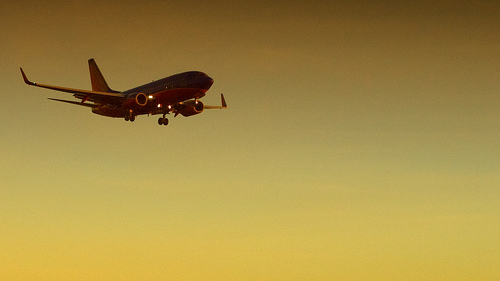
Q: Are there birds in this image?
A: No, there are no birds.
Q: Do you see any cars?
A: No, there are no cars.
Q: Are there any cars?
A: No, there are no cars.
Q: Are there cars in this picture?
A: No, there are no cars.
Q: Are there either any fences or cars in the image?
A: No, there are no cars or fences.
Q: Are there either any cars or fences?
A: No, there are no cars or fences.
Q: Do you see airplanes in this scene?
A: Yes, there is an airplane.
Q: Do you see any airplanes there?
A: Yes, there is an airplane.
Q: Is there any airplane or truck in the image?
A: Yes, there is an airplane.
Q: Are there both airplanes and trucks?
A: No, there is an airplane but no trucks.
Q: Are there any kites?
A: No, there are no kites.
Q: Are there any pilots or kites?
A: No, there are no kites or pilots.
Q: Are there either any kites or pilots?
A: No, there are no kites or pilots.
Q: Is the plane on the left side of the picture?
A: Yes, the plane is on the left of the image.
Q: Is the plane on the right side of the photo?
A: No, the plane is on the left of the image.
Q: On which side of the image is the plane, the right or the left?
A: The plane is on the left of the image.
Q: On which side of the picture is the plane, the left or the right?
A: The plane is on the left of the image.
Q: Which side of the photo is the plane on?
A: The plane is on the left of the image.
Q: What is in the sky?
A: The plane is in the sky.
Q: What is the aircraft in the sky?
A: The aircraft is an airplane.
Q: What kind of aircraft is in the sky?
A: The aircraft is an airplane.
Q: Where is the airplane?
A: The airplane is in the sky.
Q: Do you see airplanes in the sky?
A: Yes, there is an airplane in the sky.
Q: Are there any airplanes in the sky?
A: Yes, there is an airplane in the sky.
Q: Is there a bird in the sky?
A: No, there is an airplane in the sky.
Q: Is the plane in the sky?
A: Yes, the plane is in the sky.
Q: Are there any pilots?
A: No, there are no pilots.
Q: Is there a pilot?
A: No, there are no pilots.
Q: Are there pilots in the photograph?
A: No, there are no pilots.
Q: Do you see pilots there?
A: No, there are no pilots.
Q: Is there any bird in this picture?
A: No, there are no birds.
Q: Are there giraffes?
A: No, there are no giraffes.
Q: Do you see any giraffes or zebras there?
A: No, there are no giraffes or zebras.